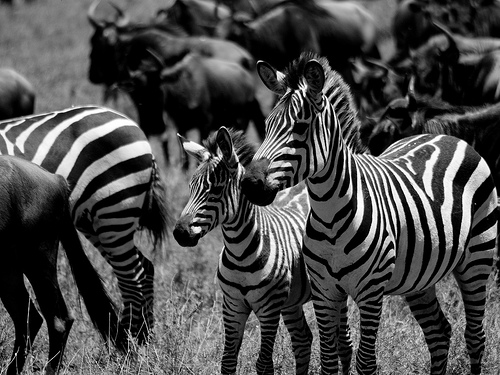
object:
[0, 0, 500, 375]
grass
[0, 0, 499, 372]
dried grass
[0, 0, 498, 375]
plain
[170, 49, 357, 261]
gold letters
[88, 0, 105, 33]
horns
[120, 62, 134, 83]
horns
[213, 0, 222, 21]
horns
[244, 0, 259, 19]
horns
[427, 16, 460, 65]
horns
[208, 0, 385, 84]
wildebeest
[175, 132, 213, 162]
ear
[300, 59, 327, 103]
ear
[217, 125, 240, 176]
ear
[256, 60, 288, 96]
ear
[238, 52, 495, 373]
zebra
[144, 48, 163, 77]
horns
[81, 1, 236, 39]
water buffalo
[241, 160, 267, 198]
black nose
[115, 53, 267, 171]
buffalo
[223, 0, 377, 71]
oxen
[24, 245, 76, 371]
leg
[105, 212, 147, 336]
leg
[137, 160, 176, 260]
tail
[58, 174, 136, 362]
tail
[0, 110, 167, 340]
zebra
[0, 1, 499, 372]
animals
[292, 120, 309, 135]
eye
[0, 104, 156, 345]
stripes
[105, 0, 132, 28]
horns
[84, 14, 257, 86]
bull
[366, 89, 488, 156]
buffalo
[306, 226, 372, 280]
stripe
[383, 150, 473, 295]
stripe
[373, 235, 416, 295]
stripe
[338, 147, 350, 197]
stripe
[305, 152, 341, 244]
stripe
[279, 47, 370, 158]
hair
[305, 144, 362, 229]
neck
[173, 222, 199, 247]
snout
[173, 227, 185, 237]
tip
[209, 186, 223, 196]
eye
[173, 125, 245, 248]
head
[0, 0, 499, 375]
field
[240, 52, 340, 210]
head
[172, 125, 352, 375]
colt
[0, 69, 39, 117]
ox